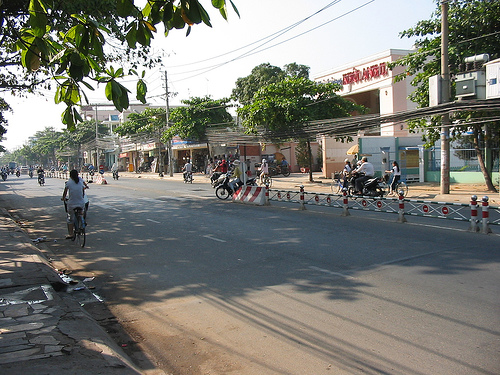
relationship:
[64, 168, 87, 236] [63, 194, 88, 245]
person riding bike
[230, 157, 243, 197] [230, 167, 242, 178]
person has shirt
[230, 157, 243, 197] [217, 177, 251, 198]
person riding moped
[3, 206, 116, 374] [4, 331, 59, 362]
pavement has stone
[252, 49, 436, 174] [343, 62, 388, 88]
building has sign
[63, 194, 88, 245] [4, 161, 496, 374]
bike on street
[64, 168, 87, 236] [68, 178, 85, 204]
person has shirt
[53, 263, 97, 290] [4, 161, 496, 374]
garbage on street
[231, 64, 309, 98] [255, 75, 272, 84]
tree has leaves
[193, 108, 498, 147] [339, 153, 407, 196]
electrical wires are above group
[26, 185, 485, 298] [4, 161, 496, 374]
shadows are on street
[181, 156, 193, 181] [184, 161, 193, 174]
man has shirt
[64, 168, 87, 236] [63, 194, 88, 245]
person on bike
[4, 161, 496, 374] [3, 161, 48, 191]
street has cyclists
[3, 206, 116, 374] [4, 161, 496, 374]
sidewalk near street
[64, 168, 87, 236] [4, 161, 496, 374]
person on street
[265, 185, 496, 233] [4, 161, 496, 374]
safety railing divides street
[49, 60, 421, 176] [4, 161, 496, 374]
stores are alongside street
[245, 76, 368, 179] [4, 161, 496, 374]
tree near street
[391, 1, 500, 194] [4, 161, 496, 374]
tree near street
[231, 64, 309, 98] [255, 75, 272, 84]
tree covered in leaves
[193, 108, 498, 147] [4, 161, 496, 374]
electrical wires are above street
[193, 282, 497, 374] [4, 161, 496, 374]
shadow on street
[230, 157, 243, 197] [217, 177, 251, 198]
person on moped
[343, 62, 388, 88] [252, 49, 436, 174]
sign on side of building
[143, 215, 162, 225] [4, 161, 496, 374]
line on street